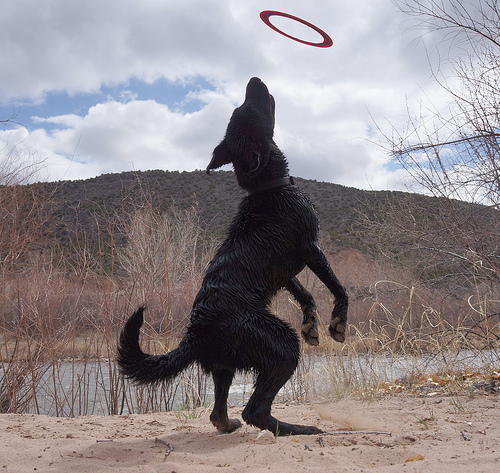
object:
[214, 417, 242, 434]
back paws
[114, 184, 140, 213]
branch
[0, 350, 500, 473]
ground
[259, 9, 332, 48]
disc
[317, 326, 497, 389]
grass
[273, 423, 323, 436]
feet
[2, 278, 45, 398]
stalks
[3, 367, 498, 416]
edge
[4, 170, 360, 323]
mountain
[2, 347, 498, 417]
lake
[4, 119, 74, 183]
puffy clouds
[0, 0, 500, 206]
blue sky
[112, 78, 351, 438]
black dog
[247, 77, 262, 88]
nose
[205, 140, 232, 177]
ears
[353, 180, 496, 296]
hills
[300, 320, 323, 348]
feet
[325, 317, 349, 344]
feet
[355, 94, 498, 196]
branch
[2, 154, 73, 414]
trees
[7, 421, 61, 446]
tracks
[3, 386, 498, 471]
sand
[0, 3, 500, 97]
clouds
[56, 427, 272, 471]
shadow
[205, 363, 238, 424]
leg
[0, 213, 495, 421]
grass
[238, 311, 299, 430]
leg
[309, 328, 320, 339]
pads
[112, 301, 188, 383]
tail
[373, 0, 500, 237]
tree